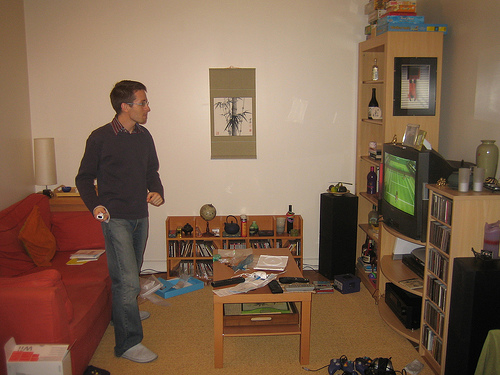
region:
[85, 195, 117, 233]
man holding Wii controller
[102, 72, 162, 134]
man wearing silver rimmed glasses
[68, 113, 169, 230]
a man wearing a dark sweater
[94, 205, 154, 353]
a man wearing blue jeans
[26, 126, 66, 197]
a lamp shade in the corner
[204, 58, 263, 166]
a picture on a white wall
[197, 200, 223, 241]
a small globe on a shelf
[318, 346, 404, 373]
game controls on the floor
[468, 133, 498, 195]
a green vase on top of a shelf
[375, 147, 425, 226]
Wii tennis on the TV screen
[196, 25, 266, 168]
painting on the wall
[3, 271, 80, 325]
arm of the couch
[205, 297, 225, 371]
leg of the table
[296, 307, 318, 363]
leg of the table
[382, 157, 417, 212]
the screen is on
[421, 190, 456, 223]
cds on the shelf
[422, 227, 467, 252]
cd on the shelf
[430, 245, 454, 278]
cd on the shelf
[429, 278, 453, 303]
cd on the shelf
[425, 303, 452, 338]
cd on the shelf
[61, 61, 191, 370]
Man in the foreground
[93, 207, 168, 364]
Man is wearing blue jeans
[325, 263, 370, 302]
A gaming system on the floor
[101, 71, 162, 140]
A side view of a man's head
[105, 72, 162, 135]
Man is wearing eyeglasses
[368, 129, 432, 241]
The TV screen is on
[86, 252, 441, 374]
The carpet on the floor is tan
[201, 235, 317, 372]
A small table in the foreground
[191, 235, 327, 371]
Table is made of wood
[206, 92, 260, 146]
Picture is on the wall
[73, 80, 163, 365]
a young man playing a game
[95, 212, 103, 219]
a Wii video game controller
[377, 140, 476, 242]
a black TV set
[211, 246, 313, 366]
a blonde wood coffee table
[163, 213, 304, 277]
a blonde wood organizer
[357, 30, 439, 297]
a blonde wood bookcase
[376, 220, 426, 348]
a blonde wood TV stand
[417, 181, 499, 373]
a blonde wood media organizer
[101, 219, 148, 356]
a pair of jeans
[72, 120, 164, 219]
a dark grey sweater